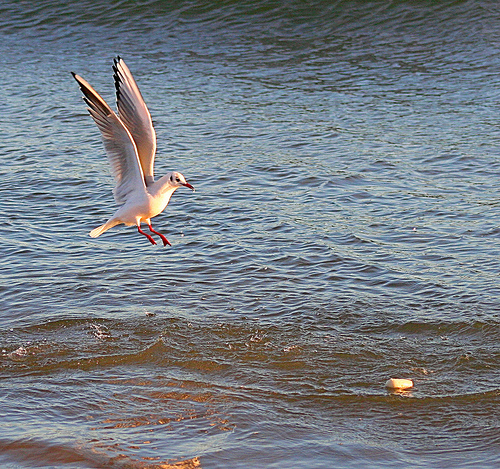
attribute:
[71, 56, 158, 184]
wings — extended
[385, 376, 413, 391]
object — unrecognizable, floating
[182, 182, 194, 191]
bill — red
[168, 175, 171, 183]
spot — black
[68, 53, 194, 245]
bird — round, white, grey and black, flying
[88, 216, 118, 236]
tail — white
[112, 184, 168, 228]
bird pumage — white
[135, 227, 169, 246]
legs — bright orange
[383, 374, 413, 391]
chunk — white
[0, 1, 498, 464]
water — body of, wavy 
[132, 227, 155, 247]
leg — bright red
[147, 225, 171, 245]
left leg — bright red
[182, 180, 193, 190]
beak — red and black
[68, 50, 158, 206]
wings — white, grey and black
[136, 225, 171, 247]
legs — red, long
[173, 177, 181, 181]
eye — black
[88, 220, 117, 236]
tail feathers — white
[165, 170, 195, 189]
head — white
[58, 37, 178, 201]
wings — a pair of, long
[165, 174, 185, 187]
eye — dark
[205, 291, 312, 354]
ripples — small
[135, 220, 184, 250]
legs — pair of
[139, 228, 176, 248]
foot — orange, webbed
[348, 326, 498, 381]
ripple — small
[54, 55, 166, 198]
wings — pair of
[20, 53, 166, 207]
wings — large, white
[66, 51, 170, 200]
wings — sticking up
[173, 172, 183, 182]
eye — black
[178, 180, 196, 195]
beak — pointy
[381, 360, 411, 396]
food — piece of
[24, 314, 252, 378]
waves — small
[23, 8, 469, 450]
water — large, body of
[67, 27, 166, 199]
wings — both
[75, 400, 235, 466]
light — orange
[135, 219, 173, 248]
legs — orange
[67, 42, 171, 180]
wings — birds, moslty white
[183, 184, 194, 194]
beak — bird's, orange